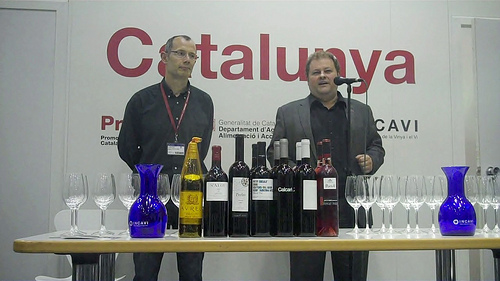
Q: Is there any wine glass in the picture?
A: Yes, there is a wine glass.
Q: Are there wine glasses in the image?
A: Yes, there is a wine glass.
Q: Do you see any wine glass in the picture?
A: Yes, there is a wine glass.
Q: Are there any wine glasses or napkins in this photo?
A: Yes, there is a wine glass.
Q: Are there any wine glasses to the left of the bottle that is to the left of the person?
A: Yes, there is a wine glass to the left of the bottle.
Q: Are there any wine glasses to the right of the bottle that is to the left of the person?
A: No, the wine glass is to the left of the bottle.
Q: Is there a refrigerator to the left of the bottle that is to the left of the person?
A: No, there is a wine glass to the left of the bottle.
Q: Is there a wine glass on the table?
A: Yes, there is a wine glass on the table.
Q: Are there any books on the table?
A: No, there is a wine glass on the table.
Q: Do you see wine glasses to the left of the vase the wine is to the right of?
A: Yes, there is a wine glass to the left of the vase.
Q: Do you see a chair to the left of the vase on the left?
A: No, there is a wine glass to the left of the vase.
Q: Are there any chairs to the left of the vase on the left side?
A: No, there is a wine glass to the left of the vase.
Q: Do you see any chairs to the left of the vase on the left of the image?
A: No, there is a wine glass to the left of the vase.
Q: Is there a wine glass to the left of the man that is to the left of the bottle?
A: Yes, there is a wine glass to the left of the man.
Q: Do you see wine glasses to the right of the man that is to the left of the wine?
A: No, the wine glass is to the left of the man.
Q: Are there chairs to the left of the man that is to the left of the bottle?
A: No, there is a wine glass to the left of the man.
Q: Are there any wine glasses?
A: Yes, there is a wine glass.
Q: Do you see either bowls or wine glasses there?
A: Yes, there is a wine glass.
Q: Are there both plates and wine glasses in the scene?
A: No, there is a wine glass but no plates.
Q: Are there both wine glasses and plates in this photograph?
A: No, there is a wine glass but no plates.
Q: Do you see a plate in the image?
A: No, there are no plates.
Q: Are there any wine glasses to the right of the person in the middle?
A: Yes, there is a wine glass to the right of the person.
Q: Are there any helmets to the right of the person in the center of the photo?
A: No, there is a wine glass to the right of the person.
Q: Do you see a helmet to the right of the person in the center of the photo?
A: No, there is a wine glass to the right of the person.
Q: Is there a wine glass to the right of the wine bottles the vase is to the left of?
A: Yes, there is a wine glass to the right of the wine bottles.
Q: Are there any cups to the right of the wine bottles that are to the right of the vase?
A: No, there is a wine glass to the right of the wine bottles.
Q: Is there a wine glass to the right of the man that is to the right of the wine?
A: Yes, there is a wine glass to the right of the man.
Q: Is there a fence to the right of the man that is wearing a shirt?
A: No, there is a wine glass to the right of the man.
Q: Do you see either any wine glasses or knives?
A: Yes, there is a wine glass.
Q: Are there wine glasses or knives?
A: Yes, there is a wine glass.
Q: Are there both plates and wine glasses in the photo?
A: No, there is a wine glass but no plates.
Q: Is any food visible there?
A: No, there is no food.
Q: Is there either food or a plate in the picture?
A: No, there are no food or plates.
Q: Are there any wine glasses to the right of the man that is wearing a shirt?
A: Yes, there is a wine glass to the right of the man.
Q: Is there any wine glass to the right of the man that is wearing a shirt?
A: Yes, there is a wine glass to the right of the man.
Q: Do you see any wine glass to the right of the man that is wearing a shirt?
A: Yes, there is a wine glass to the right of the man.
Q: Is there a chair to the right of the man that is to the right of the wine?
A: No, there is a wine glass to the right of the man.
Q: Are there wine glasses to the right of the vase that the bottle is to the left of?
A: Yes, there is a wine glass to the right of the vase.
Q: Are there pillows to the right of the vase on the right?
A: No, there is a wine glass to the right of the vase.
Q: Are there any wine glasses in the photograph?
A: Yes, there is a wine glass.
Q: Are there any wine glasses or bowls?
A: Yes, there is a wine glass.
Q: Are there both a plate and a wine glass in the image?
A: No, there is a wine glass but no plates.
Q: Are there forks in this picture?
A: No, there are no forks.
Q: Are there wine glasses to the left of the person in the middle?
A: Yes, there is a wine glass to the left of the person.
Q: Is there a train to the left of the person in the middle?
A: No, there is a wine glass to the left of the person.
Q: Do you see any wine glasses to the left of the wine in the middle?
A: Yes, there is a wine glass to the left of the wine.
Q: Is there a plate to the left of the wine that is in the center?
A: No, there is a wine glass to the left of the wine.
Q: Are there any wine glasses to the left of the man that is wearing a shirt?
A: Yes, there is a wine glass to the left of the man.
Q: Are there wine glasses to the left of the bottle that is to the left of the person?
A: Yes, there is a wine glass to the left of the bottle.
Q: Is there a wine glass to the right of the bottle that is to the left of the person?
A: No, the wine glass is to the left of the bottle.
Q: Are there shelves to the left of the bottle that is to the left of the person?
A: No, there is a wine glass to the left of the bottle.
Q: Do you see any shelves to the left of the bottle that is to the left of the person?
A: No, there is a wine glass to the left of the bottle.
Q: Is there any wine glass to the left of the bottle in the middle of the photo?
A: Yes, there is a wine glass to the left of the bottle.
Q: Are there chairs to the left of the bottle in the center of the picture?
A: No, there is a wine glass to the left of the bottle.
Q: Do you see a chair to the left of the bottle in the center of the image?
A: No, there is a wine glass to the left of the bottle.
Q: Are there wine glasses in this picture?
A: Yes, there is a wine glass.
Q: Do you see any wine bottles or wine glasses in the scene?
A: Yes, there is a wine glass.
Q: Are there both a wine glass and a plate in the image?
A: No, there is a wine glass but no plates.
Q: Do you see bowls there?
A: No, there are no bowls.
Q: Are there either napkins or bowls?
A: No, there are no bowls or napkins.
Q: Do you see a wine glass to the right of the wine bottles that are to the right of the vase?
A: Yes, there is a wine glass to the right of the wine bottles.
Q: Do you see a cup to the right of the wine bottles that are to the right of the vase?
A: No, there is a wine glass to the right of the wine bottles.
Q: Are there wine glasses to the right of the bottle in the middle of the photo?
A: Yes, there is a wine glass to the right of the bottle.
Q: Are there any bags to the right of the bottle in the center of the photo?
A: No, there is a wine glass to the right of the bottle.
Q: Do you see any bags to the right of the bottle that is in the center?
A: No, there is a wine glass to the right of the bottle.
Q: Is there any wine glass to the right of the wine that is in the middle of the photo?
A: Yes, there is a wine glass to the right of the wine.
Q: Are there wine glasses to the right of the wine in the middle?
A: Yes, there is a wine glass to the right of the wine.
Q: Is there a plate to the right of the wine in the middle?
A: No, there is a wine glass to the right of the wine.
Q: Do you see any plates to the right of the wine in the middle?
A: No, there is a wine glass to the right of the wine.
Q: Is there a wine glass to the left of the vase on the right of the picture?
A: Yes, there is a wine glass to the left of the vase.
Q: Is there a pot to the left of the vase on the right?
A: No, there is a wine glass to the left of the vase.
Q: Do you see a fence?
A: No, there are no fences.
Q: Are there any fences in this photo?
A: No, there are no fences.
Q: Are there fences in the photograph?
A: No, there are no fences.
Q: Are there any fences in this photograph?
A: No, there are no fences.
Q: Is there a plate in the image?
A: No, there are no plates.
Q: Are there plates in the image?
A: No, there are no plates.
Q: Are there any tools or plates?
A: No, there are no plates or tools.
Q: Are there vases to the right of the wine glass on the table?
A: Yes, there is a vase to the right of the wineglass.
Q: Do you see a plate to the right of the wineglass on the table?
A: No, there is a vase to the right of the wineglass.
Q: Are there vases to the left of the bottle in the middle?
A: Yes, there is a vase to the left of the bottle.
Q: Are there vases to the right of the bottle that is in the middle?
A: No, the vase is to the left of the bottle.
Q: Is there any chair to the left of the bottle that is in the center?
A: No, there is a vase to the left of the bottle.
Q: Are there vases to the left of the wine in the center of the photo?
A: Yes, there is a vase to the left of the wine.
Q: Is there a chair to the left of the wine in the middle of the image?
A: No, there is a vase to the left of the wine.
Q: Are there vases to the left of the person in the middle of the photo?
A: Yes, there is a vase to the left of the person.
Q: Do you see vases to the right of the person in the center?
A: No, the vase is to the left of the person.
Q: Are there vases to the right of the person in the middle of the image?
A: No, the vase is to the left of the person.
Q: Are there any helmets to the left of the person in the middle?
A: No, there is a vase to the left of the person.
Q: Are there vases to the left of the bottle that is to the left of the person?
A: Yes, there is a vase to the left of the bottle.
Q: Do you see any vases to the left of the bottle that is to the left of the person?
A: Yes, there is a vase to the left of the bottle.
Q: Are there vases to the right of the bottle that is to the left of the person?
A: No, the vase is to the left of the bottle.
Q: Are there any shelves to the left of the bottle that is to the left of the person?
A: No, there is a vase to the left of the bottle.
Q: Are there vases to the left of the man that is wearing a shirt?
A: Yes, there is a vase to the left of the man.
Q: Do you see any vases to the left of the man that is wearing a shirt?
A: Yes, there is a vase to the left of the man.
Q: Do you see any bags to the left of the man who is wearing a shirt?
A: No, there is a vase to the left of the man.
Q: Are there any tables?
A: Yes, there is a table.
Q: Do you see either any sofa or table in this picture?
A: Yes, there is a table.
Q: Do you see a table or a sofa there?
A: Yes, there is a table.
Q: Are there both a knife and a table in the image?
A: No, there is a table but no knives.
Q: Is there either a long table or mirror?
A: Yes, there is a long table.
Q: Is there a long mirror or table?
A: Yes, there is a long table.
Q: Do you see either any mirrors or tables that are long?
A: Yes, the table is long.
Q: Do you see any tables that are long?
A: Yes, there is a long table.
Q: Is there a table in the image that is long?
A: Yes, there is a table that is long.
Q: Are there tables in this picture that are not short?
A: Yes, there is a long table.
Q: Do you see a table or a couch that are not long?
A: No, there is a table but it is long.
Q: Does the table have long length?
A: Yes, the table is long.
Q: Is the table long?
A: Yes, the table is long.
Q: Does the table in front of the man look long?
A: Yes, the table is long.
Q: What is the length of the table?
A: The table is long.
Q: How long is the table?
A: The table is long.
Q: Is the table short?
A: No, the table is long.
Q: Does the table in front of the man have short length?
A: No, the table is long.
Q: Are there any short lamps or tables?
A: No, there is a table but it is long.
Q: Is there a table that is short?
A: No, there is a table but it is long.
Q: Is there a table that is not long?
A: No, there is a table but it is long.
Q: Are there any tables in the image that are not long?
A: No, there is a table but it is long.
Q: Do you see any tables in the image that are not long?
A: No, there is a table but it is long.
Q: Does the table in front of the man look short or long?
A: The table is long.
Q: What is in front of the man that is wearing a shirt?
A: The table is in front of the man.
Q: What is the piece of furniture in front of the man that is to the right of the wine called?
A: The piece of furniture is a table.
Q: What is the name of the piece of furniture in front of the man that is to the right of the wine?
A: The piece of furniture is a table.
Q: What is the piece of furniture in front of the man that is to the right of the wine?
A: The piece of furniture is a table.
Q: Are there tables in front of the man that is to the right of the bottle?
A: Yes, there is a table in front of the man.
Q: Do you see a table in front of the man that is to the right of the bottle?
A: Yes, there is a table in front of the man.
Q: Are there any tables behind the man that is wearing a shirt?
A: No, the table is in front of the man.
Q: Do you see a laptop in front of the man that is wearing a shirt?
A: No, there is a table in front of the man.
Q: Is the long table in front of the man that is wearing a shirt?
A: Yes, the table is in front of the man.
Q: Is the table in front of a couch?
A: No, the table is in front of the man.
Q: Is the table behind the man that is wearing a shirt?
A: No, the table is in front of the man.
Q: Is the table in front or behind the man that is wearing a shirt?
A: The table is in front of the man.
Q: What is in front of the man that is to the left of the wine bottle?
A: The table is in front of the man.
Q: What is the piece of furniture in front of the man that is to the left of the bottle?
A: The piece of furniture is a table.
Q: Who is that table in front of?
A: The table is in front of the man.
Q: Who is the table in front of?
A: The table is in front of the man.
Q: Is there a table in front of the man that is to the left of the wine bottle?
A: Yes, there is a table in front of the man.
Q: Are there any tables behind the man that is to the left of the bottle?
A: No, the table is in front of the man.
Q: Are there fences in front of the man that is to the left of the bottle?
A: No, there is a table in front of the man.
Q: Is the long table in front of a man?
A: Yes, the table is in front of a man.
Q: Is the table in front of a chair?
A: No, the table is in front of a man.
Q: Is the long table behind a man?
A: No, the table is in front of a man.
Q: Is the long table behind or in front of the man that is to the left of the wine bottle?
A: The table is in front of the man.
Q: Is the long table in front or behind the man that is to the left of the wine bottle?
A: The table is in front of the man.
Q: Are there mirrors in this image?
A: No, there are no mirrors.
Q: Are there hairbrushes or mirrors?
A: No, there are no mirrors or hairbrushes.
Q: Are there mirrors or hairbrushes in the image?
A: No, there are no mirrors or hairbrushes.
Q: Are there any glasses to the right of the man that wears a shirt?
A: Yes, there are glasses to the right of the man.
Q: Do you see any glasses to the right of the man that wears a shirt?
A: Yes, there are glasses to the right of the man.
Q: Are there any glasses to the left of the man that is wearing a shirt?
A: No, the glasses are to the right of the man.